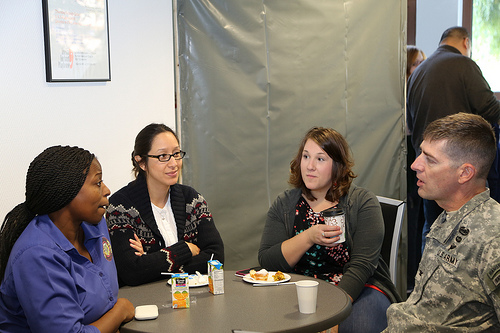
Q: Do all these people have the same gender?
A: No, they are both male and female.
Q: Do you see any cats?
A: No, there are no cats.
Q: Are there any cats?
A: No, there are no cats.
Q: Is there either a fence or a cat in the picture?
A: No, there are no cats or fences.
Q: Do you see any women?
A: Yes, there is a woman.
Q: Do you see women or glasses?
A: Yes, there is a woman.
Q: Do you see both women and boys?
A: No, there is a woman but no boys.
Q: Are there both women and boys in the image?
A: No, there is a woman but no boys.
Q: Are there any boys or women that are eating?
A: Yes, the woman is eating.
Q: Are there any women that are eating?
A: Yes, there is a woman that is eating.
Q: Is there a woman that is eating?
A: Yes, there is a woman that is eating.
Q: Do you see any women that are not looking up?
A: Yes, there is a woman that is eating .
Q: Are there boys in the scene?
A: No, there are no boys.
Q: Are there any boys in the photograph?
A: No, there are no boys.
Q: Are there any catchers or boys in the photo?
A: No, there are no boys or catchers.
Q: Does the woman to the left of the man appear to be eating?
A: Yes, the woman is eating.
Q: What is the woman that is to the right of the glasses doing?
A: The woman is eating.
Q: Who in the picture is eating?
A: The woman is eating.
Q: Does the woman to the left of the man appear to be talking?
A: No, the woman is eating.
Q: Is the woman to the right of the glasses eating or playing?
A: The woman is eating.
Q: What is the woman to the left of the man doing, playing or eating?
A: The woman is eating.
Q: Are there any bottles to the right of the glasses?
A: No, there is a woman to the right of the glasses.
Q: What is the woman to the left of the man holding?
A: The woman is holding the cup.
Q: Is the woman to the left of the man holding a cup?
A: Yes, the woman is holding a cup.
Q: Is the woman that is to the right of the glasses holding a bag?
A: No, the woman is holding a cup.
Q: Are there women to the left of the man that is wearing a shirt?
A: Yes, there is a woman to the left of the man.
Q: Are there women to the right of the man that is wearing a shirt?
A: No, the woman is to the left of the man.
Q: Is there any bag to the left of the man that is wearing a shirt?
A: No, there is a woman to the left of the man.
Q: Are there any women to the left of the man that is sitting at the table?
A: Yes, there is a woman to the left of the man.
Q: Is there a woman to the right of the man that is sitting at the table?
A: No, the woman is to the left of the man.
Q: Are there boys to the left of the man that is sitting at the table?
A: No, there is a woman to the left of the man.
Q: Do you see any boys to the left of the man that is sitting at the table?
A: No, there is a woman to the left of the man.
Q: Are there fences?
A: No, there are no fences.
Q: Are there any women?
A: Yes, there is a woman.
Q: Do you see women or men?
A: Yes, there is a woman.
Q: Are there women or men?
A: Yes, there is a woman.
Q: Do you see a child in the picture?
A: No, there are no children.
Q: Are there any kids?
A: No, there are no kids.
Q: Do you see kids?
A: No, there are no kids.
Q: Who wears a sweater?
A: The woman wears a sweater.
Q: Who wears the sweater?
A: The woman wears a sweater.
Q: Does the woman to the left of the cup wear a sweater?
A: Yes, the woman wears a sweater.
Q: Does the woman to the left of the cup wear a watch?
A: No, the woman wears a sweater.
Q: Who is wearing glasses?
A: The woman is wearing glasses.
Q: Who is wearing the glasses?
A: The woman is wearing glasses.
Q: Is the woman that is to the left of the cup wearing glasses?
A: Yes, the woman is wearing glasses.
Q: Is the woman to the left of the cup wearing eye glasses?
A: No, the woman is wearing glasses.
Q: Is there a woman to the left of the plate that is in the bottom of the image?
A: Yes, there is a woman to the left of the plate.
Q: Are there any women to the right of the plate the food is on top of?
A: No, the woman is to the left of the plate.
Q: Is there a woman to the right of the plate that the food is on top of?
A: No, the woman is to the left of the plate.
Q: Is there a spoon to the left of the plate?
A: No, there is a woman to the left of the plate.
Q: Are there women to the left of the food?
A: Yes, there is a woman to the left of the food.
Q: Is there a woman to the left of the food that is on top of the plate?
A: Yes, there is a woman to the left of the food.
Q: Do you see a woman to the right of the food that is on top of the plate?
A: No, the woman is to the left of the food.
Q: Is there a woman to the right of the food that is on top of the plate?
A: No, the woman is to the left of the food.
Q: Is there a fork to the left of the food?
A: No, there is a woman to the left of the food.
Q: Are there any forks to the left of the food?
A: No, there is a woman to the left of the food.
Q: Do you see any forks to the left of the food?
A: No, there is a woman to the left of the food.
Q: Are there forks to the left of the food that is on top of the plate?
A: No, there is a woman to the left of the food.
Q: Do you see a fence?
A: No, there are no fences.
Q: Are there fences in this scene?
A: No, there are no fences.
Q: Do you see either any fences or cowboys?
A: No, there are no fences or cowboys.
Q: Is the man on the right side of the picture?
A: Yes, the man is on the right of the image.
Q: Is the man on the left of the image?
A: No, the man is on the right of the image.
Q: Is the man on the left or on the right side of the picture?
A: The man is on the right of the image.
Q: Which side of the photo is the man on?
A: The man is on the right of the image.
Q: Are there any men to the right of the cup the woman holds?
A: Yes, there is a man to the right of the cup.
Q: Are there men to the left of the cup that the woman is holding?
A: No, the man is to the right of the cup.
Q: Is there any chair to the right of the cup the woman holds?
A: No, there is a man to the right of the cup.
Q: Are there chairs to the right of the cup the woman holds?
A: No, there is a man to the right of the cup.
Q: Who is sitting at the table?
A: The man is sitting at the table.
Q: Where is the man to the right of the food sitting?
A: The man is sitting at the table.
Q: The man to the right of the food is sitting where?
A: The man is sitting at the table.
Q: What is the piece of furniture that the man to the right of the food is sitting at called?
A: The piece of furniture is a table.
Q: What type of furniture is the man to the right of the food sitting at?
A: The man is sitting at the table.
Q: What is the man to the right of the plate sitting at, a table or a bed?
A: The man is sitting at a table.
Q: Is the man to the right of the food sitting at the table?
A: Yes, the man is sitting at the table.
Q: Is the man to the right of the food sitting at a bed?
A: No, the man is sitting at the table.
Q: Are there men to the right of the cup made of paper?
A: Yes, there is a man to the right of the cup.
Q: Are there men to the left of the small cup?
A: No, the man is to the right of the cup.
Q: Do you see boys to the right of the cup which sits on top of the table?
A: No, there is a man to the right of the cup.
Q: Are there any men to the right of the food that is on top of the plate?
A: Yes, there is a man to the right of the food.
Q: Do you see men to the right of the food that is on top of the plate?
A: Yes, there is a man to the right of the food.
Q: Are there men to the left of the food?
A: No, the man is to the right of the food.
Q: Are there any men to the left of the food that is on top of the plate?
A: No, the man is to the right of the food.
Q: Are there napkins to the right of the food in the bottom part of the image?
A: No, there is a man to the right of the food.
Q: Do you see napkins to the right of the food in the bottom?
A: No, there is a man to the right of the food.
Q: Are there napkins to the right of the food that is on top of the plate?
A: No, there is a man to the right of the food.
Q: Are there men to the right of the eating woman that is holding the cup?
A: Yes, there is a man to the right of the woman.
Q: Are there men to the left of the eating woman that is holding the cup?
A: No, the man is to the right of the woman.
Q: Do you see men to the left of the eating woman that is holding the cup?
A: No, the man is to the right of the woman.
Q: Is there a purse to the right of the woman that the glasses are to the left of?
A: No, there is a man to the right of the woman.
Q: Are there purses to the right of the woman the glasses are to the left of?
A: No, there is a man to the right of the woman.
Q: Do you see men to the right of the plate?
A: Yes, there is a man to the right of the plate.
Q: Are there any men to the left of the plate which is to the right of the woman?
A: No, the man is to the right of the plate.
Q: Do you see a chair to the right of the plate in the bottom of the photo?
A: No, there is a man to the right of the plate.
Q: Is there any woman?
A: Yes, there is a woman.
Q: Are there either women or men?
A: Yes, there is a woman.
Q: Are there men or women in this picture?
A: Yes, there is a woman.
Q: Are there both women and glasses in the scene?
A: Yes, there are both a woman and glasses.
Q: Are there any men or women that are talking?
A: Yes, the woman is talking.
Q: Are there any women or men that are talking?
A: Yes, the woman is talking.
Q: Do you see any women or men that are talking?
A: Yes, the woman is talking.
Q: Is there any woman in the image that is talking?
A: Yes, there is a woman that is talking.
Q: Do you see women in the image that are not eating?
A: Yes, there is a woman that is talking .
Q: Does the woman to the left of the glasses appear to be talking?
A: Yes, the woman is talking.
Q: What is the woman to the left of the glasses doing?
A: The woman is talking.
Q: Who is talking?
A: The woman is talking.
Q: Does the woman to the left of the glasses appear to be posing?
A: No, the woman is talking.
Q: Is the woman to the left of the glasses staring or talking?
A: The woman is talking.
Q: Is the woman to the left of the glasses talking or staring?
A: The woman is talking.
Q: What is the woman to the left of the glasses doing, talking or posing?
A: The woman is talking.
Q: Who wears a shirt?
A: The woman wears a shirt.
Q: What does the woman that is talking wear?
A: The woman wears a shirt.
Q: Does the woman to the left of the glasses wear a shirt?
A: Yes, the woman wears a shirt.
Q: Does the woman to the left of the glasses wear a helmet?
A: No, the woman wears a shirt.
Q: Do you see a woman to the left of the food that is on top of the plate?
A: Yes, there is a woman to the left of the food.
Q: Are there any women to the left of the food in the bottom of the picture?
A: Yes, there is a woman to the left of the food.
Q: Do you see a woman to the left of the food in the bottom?
A: Yes, there is a woman to the left of the food.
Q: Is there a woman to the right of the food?
A: No, the woman is to the left of the food.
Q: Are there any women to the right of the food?
A: No, the woman is to the left of the food.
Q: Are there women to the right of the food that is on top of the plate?
A: No, the woman is to the left of the food.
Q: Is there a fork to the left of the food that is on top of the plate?
A: No, there is a woman to the left of the food.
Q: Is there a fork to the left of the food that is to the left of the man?
A: No, there is a woman to the left of the food.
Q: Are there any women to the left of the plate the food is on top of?
A: Yes, there is a woman to the left of the plate.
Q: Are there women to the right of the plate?
A: No, the woman is to the left of the plate.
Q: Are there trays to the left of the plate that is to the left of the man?
A: No, there is a woman to the left of the plate.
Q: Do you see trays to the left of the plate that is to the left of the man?
A: No, there is a woman to the left of the plate.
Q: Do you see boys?
A: No, there are no boys.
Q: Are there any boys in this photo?
A: No, there are no boys.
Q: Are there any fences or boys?
A: No, there are no boys or fences.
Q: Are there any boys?
A: No, there are no boys.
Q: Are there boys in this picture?
A: No, there are no boys.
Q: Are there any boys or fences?
A: No, there are no boys or fences.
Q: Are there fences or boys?
A: No, there are no boys or fences.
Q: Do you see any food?
A: Yes, there is food.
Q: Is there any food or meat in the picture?
A: Yes, there is food.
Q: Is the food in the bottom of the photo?
A: Yes, the food is in the bottom of the image.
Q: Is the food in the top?
A: No, the food is in the bottom of the image.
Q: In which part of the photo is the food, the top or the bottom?
A: The food is in the bottom of the image.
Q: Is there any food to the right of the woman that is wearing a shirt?
A: Yes, there is food to the right of the woman.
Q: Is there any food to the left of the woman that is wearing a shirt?
A: No, the food is to the right of the woman.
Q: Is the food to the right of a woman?
A: Yes, the food is to the right of a woman.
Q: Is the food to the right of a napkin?
A: No, the food is to the right of a woman.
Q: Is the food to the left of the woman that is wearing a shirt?
A: No, the food is to the right of the woman.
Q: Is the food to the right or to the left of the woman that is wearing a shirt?
A: The food is to the right of the woman.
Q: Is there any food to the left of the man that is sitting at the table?
A: Yes, there is food to the left of the man.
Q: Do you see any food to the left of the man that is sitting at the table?
A: Yes, there is food to the left of the man.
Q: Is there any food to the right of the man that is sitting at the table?
A: No, the food is to the left of the man.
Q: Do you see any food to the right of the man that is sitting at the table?
A: No, the food is to the left of the man.